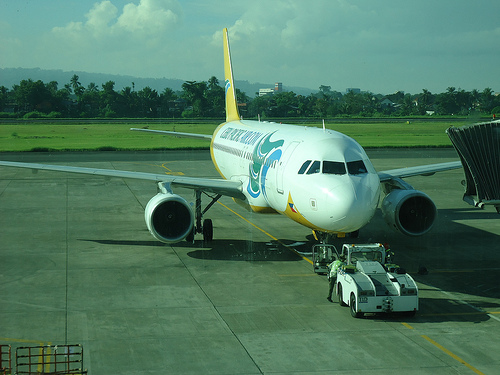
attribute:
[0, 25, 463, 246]
airplane — white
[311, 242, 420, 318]
vehicle — truck, white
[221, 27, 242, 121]
tail — yellow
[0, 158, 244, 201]
wing — gray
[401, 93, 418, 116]
tree — green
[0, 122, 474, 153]
area — grassy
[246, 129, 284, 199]
logo — blue, green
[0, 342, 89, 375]
luggage cart — parked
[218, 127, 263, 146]
lettering — dark blue